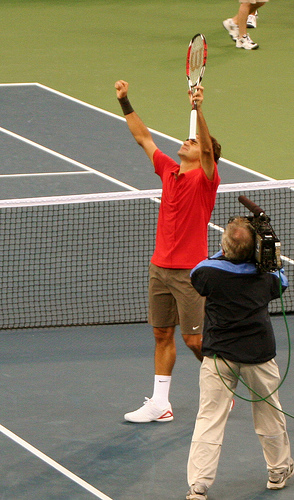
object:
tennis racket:
[181, 26, 204, 142]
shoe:
[123, 401, 182, 424]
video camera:
[229, 190, 280, 262]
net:
[2, 176, 292, 329]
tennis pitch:
[1, 82, 291, 499]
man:
[112, 78, 234, 428]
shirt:
[148, 146, 220, 269]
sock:
[146, 373, 174, 405]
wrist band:
[117, 98, 133, 116]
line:
[1, 126, 141, 193]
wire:
[208, 270, 290, 420]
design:
[156, 411, 173, 421]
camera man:
[175, 220, 290, 499]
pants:
[187, 355, 291, 494]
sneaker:
[222, 19, 240, 40]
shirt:
[188, 254, 290, 363]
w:
[188, 48, 202, 69]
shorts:
[146, 267, 206, 336]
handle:
[188, 86, 204, 141]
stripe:
[187, 257, 289, 289]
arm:
[118, 98, 172, 169]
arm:
[193, 105, 221, 185]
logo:
[157, 378, 170, 386]